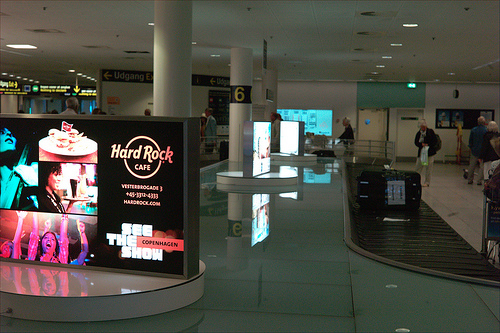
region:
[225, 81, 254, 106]
a black sign with a yellow 6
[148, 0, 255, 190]
two white support poles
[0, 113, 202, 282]
an electronic advertisement sign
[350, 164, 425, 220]
a black piece of luggage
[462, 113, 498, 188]
a man and a woman stand together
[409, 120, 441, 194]
a person holding a white bag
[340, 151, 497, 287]
a baggage conveyor belt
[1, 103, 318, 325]
three advertising signs on circle podiums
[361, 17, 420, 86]
five round recessed lights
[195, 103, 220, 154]
a man and woman walking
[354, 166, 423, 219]
Black suitcase on conveyor belt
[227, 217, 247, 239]
Reflection of number 6 in floor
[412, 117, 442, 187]
Person in black coat carrying white bag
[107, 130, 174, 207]
Hard Rock Cafe sign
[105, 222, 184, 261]
See The Show Copenhagen sign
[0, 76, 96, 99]
Lighted terminal information signs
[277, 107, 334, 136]
Bluish green lighted sign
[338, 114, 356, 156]
Person leaning on gray fence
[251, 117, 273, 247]
Lighted sign with reflection on floor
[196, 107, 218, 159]
People standing in background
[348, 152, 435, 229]
a bag on coveyor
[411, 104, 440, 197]
a woman is waiting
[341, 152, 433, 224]
the suitcase is black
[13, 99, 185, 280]
the ad is illuminated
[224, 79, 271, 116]
the number is 6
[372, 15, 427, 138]
the lights are on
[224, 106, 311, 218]
the ads are illuminated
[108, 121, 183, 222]
an ad on hard rock cafe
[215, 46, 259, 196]
the column is white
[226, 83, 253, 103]
Location marker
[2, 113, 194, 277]
Electronic advertisement display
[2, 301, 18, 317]
Electrical outlet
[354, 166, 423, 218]
Black suitcase on a conveyor belt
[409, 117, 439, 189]
Traveler waiting for luggage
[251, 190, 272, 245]
Reflection of advertisement on tile floor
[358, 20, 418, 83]
Overhead lights that are on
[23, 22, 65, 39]
Vent in the ceiling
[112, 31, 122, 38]
Overhead sprinkler in the ceiling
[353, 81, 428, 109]
Green awning above the doorway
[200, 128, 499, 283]
Carousel in an airport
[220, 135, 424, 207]
Bags on the carousel belt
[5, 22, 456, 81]
Lights on the ceiling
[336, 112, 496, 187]
People in the airport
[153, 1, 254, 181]
White pillars in the lobby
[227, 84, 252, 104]
Sign on the pillar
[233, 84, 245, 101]
Number on the sign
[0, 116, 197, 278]
Advertisement light box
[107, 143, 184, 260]
Words on the advertisement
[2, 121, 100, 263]
Pictures on the advertisement